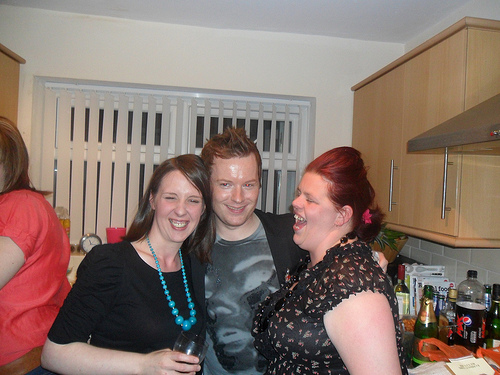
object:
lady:
[38, 153, 216, 375]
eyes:
[295, 191, 316, 204]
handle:
[387, 157, 398, 213]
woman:
[0, 110, 73, 375]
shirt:
[0, 188, 72, 375]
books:
[401, 262, 456, 316]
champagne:
[408, 285, 440, 368]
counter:
[368, 233, 499, 375]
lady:
[250, 146, 409, 375]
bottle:
[451, 269, 486, 355]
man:
[189, 125, 307, 375]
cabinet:
[349, 15, 500, 250]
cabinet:
[349, 78, 403, 222]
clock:
[78, 232, 102, 255]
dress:
[46, 238, 209, 375]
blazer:
[190, 208, 306, 374]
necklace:
[144, 233, 197, 331]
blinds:
[31, 74, 319, 247]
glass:
[170, 331, 210, 375]